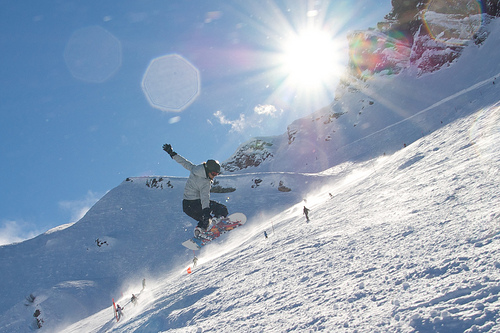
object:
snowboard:
[180, 212, 248, 254]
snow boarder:
[154, 140, 246, 251]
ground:
[50, 77, 498, 333]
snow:
[83, 105, 499, 331]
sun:
[260, 20, 356, 94]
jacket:
[167, 148, 219, 208]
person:
[301, 202, 313, 223]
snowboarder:
[160, 143, 235, 235]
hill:
[1, 171, 335, 332]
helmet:
[203, 160, 224, 176]